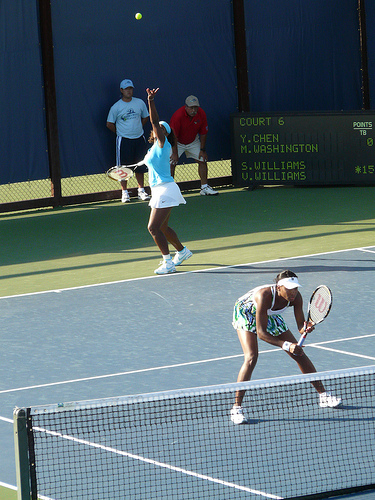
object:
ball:
[133, 11, 142, 22]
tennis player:
[141, 86, 193, 275]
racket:
[295, 284, 332, 346]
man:
[105, 79, 149, 204]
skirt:
[146, 181, 187, 210]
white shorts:
[176, 135, 206, 161]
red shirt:
[165, 107, 209, 146]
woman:
[229, 269, 342, 426]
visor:
[281, 279, 304, 291]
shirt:
[142, 133, 176, 188]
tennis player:
[228, 268, 342, 426]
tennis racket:
[105, 158, 143, 182]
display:
[231, 115, 374, 188]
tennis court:
[0, 0, 374, 499]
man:
[169, 94, 219, 196]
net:
[11, 362, 374, 499]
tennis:
[0, 0, 374, 499]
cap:
[183, 94, 199, 110]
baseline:
[0, 244, 374, 300]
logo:
[314, 291, 327, 314]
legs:
[146, 204, 170, 261]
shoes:
[152, 258, 177, 275]